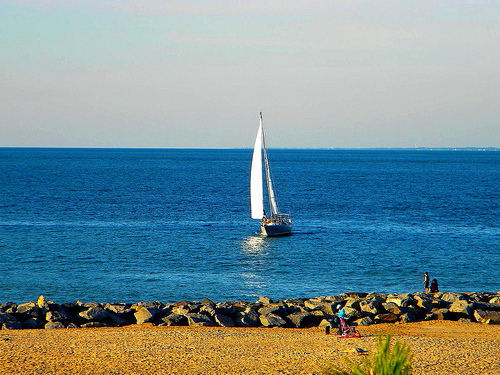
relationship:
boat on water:
[248, 107, 300, 240] [1, 148, 499, 293]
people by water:
[421, 269, 445, 294] [1, 148, 499, 293]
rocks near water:
[1, 296, 499, 329] [1, 148, 499, 293]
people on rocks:
[421, 269, 445, 294] [1, 296, 499, 329]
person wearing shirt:
[327, 303, 360, 339] [337, 312, 348, 322]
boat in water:
[248, 107, 300, 240] [1, 148, 499, 293]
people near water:
[421, 269, 445, 294] [1, 148, 499, 293]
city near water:
[229, 146, 500, 153] [1, 148, 499, 293]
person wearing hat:
[327, 303, 360, 339] [333, 302, 341, 310]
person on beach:
[327, 303, 360, 339] [4, 329, 499, 374]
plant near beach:
[308, 334, 428, 375] [4, 329, 499, 374]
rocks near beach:
[1, 296, 499, 329] [4, 329, 499, 374]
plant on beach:
[308, 334, 428, 375] [4, 329, 499, 374]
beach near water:
[4, 329, 499, 374] [1, 148, 499, 293]